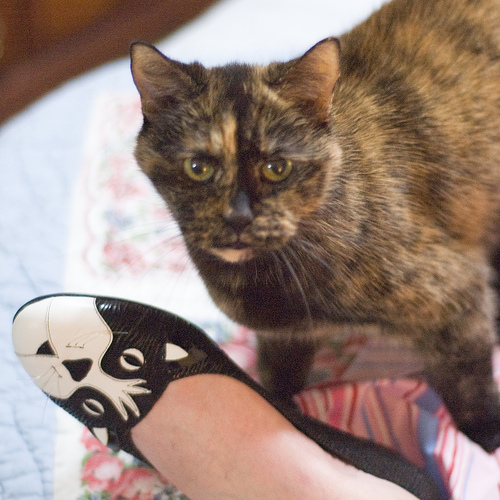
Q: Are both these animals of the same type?
A: Yes, all the animals are cats.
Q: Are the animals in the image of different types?
A: No, all the animals are cats.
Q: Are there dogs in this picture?
A: No, there are no dogs.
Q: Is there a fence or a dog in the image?
A: No, there are no dogs or fences.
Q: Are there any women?
A: Yes, there is a woman.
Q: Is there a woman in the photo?
A: Yes, there is a woman.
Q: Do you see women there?
A: Yes, there is a woman.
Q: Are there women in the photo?
A: Yes, there is a woman.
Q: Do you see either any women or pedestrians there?
A: Yes, there is a woman.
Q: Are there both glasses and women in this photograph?
A: No, there is a woman but no glasses.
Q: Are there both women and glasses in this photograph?
A: No, there is a woman but no glasses.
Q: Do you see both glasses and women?
A: No, there is a woman but no glasses.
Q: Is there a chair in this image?
A: No, there are no chairs.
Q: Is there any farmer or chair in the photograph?
A: No, there are no chairs or farmers.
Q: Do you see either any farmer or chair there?
A: No, there are no chairs or farmers.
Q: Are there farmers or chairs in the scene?
A: No, there are no chairs or farmers.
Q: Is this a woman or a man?
A: This is a woman.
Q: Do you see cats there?
A: Yes, there is a cat.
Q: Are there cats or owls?
A: Yes, there is a cat.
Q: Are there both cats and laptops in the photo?
A: No, there is a cat but no laptops.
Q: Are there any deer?
A: No, there are no deer.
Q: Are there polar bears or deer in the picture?
A: No, there are no deer or polar bears.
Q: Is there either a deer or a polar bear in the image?
A: No, there are no deer or polar bears.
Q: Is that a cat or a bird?
A: That is a cat.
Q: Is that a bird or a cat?
A: That is a cat.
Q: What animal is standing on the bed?
A: The cat is standing on the bed.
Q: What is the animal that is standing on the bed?
A: The animal is a cat.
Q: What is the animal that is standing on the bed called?
A: The animal is a cat.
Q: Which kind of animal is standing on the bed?
A: The animal is a cat.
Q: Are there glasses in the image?
A: No, there are no glasses.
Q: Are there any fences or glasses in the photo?
A: No, there are no glasses or fences.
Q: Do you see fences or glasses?
A: No, there are no glasses or fences.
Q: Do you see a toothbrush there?
A: No, there are no toothbrushes.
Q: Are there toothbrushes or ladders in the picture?
A: No, there are no toothbrushes or ladders.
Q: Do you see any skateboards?
A: No, there are no skateboards.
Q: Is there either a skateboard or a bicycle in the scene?
A: No, there are no skateboards or bicycles.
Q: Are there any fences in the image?
A: No, there are no fences.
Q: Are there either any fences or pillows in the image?
A: No, there are no fences or pillows.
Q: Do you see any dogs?
A: No, there are no dogs.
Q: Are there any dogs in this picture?
A: No, there are no dogs.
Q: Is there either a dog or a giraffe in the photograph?
A: No, there are no dogs or giraffes.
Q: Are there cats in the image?
A: Yes, there is a cat.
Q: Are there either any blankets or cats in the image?
A: Yes, there is a cat.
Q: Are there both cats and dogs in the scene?
A: No, there is a cat but no dogs.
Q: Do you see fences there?
A: No, there are no fences.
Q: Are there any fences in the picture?
A: No, there are no fences.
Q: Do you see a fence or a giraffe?
A: No, there are no fences or giraffes.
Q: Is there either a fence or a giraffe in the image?
A: No, there are no fences or giraffes.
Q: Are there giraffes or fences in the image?
A: No, there are no fences or giraffes.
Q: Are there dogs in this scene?
A: No, there are no dogs.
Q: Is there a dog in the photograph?
A: No, there are no dogs.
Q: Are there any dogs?
A: No, there are no dogs.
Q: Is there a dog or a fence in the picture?
A: No, there are no dogs or fences.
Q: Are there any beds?
A: Yes, there is a bed.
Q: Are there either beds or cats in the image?
A: Yes, there is a bed.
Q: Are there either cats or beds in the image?
A: Yes, there is a bed.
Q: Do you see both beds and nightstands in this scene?
A: No, there is a bed but no nightstands.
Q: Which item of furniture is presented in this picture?
A: The piece of furniture is a bed.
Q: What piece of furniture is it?
A: The piece of furniture is a bed.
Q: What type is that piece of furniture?
A: This is a bed.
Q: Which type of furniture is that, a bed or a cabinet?
A: This is a bed.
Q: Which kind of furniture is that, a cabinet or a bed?
A: This is a bed.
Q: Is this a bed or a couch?
A: This is a bed.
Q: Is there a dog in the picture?
A: No, there are no dogs.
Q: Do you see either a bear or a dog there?
A: No, there are no dogs or bears.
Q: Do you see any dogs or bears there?
A: No, there are no dogs or bears.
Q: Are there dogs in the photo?
A: No, there are no dogs.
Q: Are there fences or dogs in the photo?
A: No, there are no dogs or fences.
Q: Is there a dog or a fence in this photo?
A: No, there are no dogs or fences.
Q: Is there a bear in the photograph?
A: No, there are no bears.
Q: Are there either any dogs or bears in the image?
A: No, there are no bears or dogs.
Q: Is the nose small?
A: Yes, the nose is small.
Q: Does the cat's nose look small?
A: Yes, the nose is small.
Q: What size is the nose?
A: The nose is small.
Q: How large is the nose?
A: The nose is small.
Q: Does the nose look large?
A: No, the nose is small.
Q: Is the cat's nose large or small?
A: The nose is small.